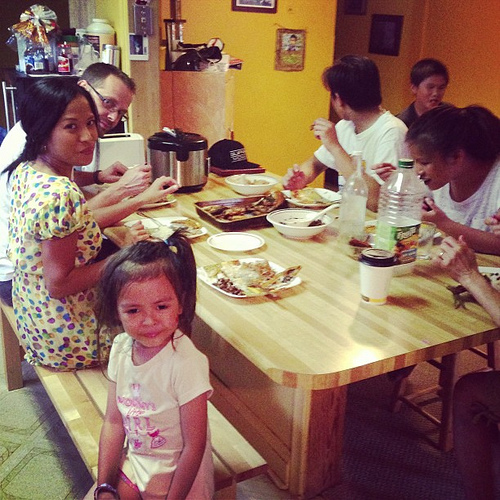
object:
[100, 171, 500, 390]
table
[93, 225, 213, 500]
girl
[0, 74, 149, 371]
lady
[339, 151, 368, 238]
bottle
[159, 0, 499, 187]
wall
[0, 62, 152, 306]
man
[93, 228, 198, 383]
hair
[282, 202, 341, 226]
spoon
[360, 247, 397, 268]
lid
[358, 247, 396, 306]
cup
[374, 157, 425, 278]
bottle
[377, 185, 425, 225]
surface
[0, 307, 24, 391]
leg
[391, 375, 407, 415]
leg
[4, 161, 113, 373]
dress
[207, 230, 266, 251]
plate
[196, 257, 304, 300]
plate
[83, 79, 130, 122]
eyeglass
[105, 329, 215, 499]
shirt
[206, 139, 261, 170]
cap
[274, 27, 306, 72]
picture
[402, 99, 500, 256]
woman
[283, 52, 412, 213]
guy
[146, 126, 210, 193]
rice cooker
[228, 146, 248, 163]
design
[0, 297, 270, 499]
bench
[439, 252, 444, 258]
ring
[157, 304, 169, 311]
eye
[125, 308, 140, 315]
eye